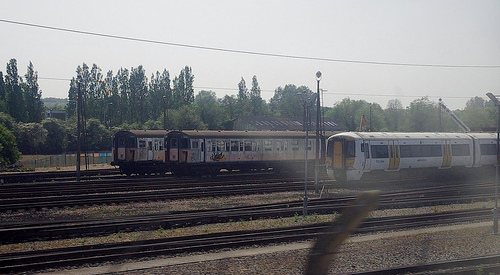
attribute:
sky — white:
[169, 10, 329, 45]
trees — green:
[89, 80, 251, 122]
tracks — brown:
[68, 184, 219, 242]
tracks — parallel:
[26, 174, 193, 236]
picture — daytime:
[49, 87, 466, 252]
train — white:
[326, 121, 464, 183]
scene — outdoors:
[29, 23, 447, 230]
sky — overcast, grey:
[191, 13, 402, 75]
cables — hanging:
[91, 16, 405, 100]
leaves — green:
[95, 69, 387, 147]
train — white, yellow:
[338, 131, 499, 188]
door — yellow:
[338, 131, 499, 188]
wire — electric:
[31, 17, 456, 109]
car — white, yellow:
[322, 134, 490, 195]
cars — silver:
[118, 120, 322, 190]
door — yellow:
[366, 143, 420, 187]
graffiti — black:
[176, 133, 310, 175]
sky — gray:
[25, 9, 355, 113]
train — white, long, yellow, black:
[324, 122, 499, 187]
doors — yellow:
[330, 137, 456, 177]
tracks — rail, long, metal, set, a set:
[3, 161, 500, 266]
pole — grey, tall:
[67, 71, 92, 190]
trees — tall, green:
[0, 51, 500, 170]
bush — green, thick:
[3, 124, 24, 164]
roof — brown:
[238, 117, 344, 131]